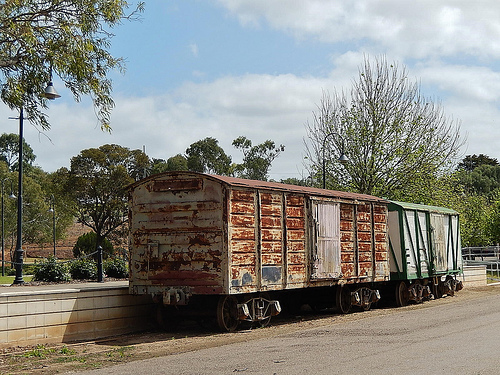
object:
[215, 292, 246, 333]
wheel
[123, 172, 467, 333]
train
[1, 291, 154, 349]
wall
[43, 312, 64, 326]
bricks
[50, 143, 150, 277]
tree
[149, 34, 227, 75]
distance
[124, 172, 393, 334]
box car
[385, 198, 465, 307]
new box car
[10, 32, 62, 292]
streetlight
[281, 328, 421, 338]
chain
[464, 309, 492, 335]
path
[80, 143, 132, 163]
top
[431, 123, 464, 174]
branches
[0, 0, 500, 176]
sky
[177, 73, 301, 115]
clouds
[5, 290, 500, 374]
road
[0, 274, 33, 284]
grass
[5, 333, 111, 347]
bottom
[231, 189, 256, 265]
rust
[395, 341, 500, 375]
litter free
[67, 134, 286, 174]
row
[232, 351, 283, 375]
dirt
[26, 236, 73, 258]
fevce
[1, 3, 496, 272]
sceme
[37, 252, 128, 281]
bushes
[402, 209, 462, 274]
greem am white